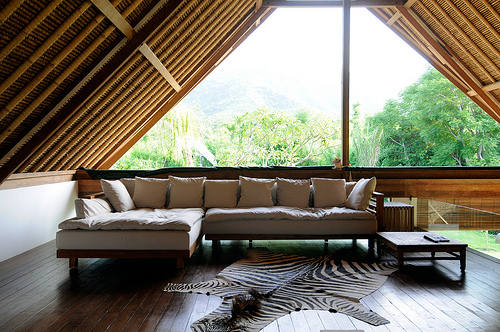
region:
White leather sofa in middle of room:
[47, 135, 397, 260]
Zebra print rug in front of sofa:
[155, 237, 401, 324]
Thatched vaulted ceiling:
[0, 0, 495, 113]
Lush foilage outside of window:
[90, 88, 492, 160]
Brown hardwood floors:
[0, 225, 491, 321]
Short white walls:
[0, 161, 90, 273]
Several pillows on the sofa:
[90, 120, 373, 210]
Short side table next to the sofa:
[371, 213, 481, 283]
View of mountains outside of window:
[180, 51, 395, 137]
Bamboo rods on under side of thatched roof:
[6, 52, 216, 162]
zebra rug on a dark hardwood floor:
[164, 270, 389, 330]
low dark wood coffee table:
[378, 230, 470, 277]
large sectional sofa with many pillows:
[56, 172, 381, 267]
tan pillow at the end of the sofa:
[352, 175, 377, 214]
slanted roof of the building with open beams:
[3, 4, 162, 126]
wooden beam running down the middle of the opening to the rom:
[325, 5, 360, 172]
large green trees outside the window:
[365, 82, 482, 164]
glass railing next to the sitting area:
[409, 196, 498, 239]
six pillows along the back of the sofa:
[127, 178, 349, 205]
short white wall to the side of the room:
[4, 195, 55, 250]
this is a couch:
[203, 172, 300, 242]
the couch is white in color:
[262, 200, 281, 223]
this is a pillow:
[316, 177, 342, 198]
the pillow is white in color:
[319, 182, 340, 192]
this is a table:
[370, 227, 447, 279]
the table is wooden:
[394, 237, 421, 255]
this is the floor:
[82, 277, 143, 325]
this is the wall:
[15, 187, 53, 242]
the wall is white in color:
[11, 197, 31, 229]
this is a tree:
[421, 86, 472, 162]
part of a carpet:
[338, 294, 365, 327]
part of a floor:
[151, 300, 163, 314]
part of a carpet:
[320, 272, 330, 287]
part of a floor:
[132, 275, 162, 321]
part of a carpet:
[288, 249, 308, 281]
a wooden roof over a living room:
[3, 3, 498, 171]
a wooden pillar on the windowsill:
[341, 3, 352, 168]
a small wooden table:
[376, 225, 471, 275]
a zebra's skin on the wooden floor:
[164, 248, 395, 329]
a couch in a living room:
[53, 175, 380, 274]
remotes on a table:
[425, 233, 449, 243]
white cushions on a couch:
[100, 173, 376, 212]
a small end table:
[376, 200, 413, 230]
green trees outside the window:
[113, 67, 497, 168]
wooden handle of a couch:
[368, 190, 385, 221]